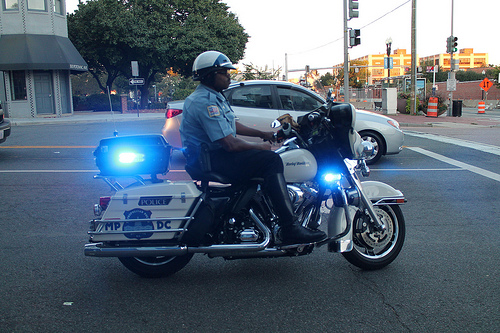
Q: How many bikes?
A: 1.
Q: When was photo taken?
A: During day.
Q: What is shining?
A: Sun.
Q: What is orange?
A: A sign.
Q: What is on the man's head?
A: Helmet.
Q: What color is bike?
A: White.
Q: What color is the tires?
A: Black.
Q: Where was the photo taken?
A: At an intersection in a city.